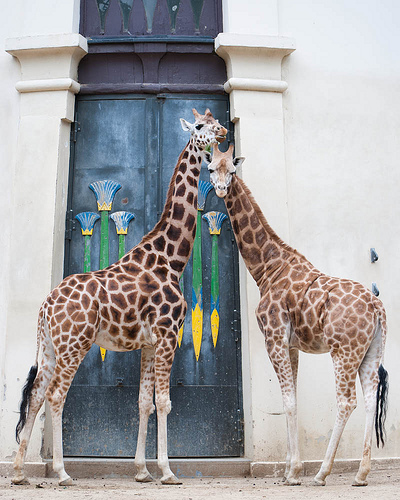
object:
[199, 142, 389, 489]
giraffe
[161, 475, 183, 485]
hoof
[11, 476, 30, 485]
hoof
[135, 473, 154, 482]
hoof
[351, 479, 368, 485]
hoof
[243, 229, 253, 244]
spot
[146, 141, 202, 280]
laptop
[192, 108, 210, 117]
horns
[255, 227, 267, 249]
brown spot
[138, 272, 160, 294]
brown spot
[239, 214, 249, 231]
brown spot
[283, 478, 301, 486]
hoof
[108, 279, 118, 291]
spot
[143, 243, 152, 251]
spot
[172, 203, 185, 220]
spot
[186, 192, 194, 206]
spot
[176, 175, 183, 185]
spot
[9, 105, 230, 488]
giraffe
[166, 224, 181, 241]
spot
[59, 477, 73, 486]
hoof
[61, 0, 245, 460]
door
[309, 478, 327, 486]
hoof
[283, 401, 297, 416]
knee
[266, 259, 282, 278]
spot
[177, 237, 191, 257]
spot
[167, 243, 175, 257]
spot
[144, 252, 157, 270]
spot